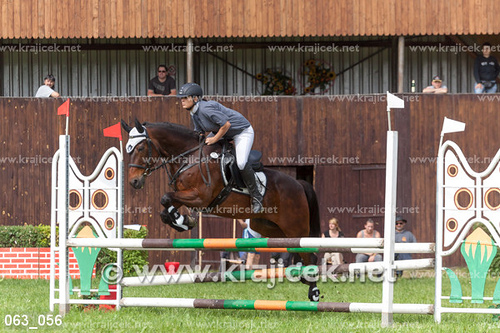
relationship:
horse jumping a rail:
[125, 118, 327, 228] [115, 222, 390, 314]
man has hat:
[379, 212, 414, 273] [175, 77, 215, 109]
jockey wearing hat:
[168, 69, 280, 183] [176, 82, 203, 100]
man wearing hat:
[384, 215, 419, 261] [393, 216, 408, 226]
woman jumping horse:
[174, 82, 277, 189] [111, 117, 346, 302]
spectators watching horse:
[12, 38, 497, 92] [118, 114, 325, 302]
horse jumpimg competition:
[118, 114, 325, 302] [32, 60, 409, 331]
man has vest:
[354, 217, 381, 263] [204, 102, 244, 138]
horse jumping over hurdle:
[118, 114, 325, 302] [67, 291, 429, 317]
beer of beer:
[410, 79, 415, 93] [410, 79, 416, 87]